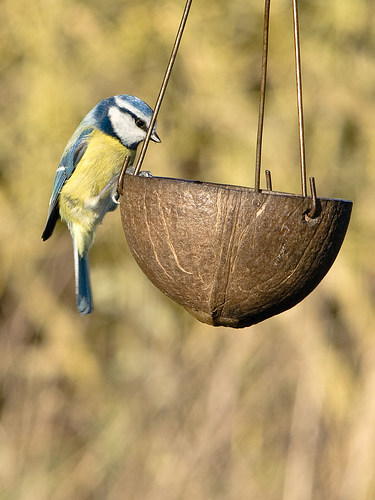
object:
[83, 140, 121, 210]
breast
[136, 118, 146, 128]
eye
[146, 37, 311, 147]
visible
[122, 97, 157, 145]
face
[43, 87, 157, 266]
colorful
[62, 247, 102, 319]
long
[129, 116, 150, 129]
small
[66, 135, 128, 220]
yellow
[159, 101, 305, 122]
hangers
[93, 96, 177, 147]
head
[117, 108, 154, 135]
stripe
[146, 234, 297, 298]
birdfeeder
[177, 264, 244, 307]
nut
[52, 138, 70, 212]
one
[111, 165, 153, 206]
bird's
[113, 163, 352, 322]
pot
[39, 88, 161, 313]
bird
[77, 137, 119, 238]
color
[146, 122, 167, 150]
beak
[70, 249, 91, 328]
tail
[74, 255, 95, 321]
color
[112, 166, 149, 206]
legs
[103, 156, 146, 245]
color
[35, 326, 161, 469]
plants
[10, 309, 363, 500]
background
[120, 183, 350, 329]
shaped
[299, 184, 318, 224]
holder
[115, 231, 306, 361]
feeder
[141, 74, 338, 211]
swing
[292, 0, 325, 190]
poles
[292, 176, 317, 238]
hole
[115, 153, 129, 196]
hook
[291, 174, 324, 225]
hook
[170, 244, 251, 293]
texture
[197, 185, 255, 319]
patch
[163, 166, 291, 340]
center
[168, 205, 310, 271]
lines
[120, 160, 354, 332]
bowl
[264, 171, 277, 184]
hook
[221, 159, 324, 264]
view